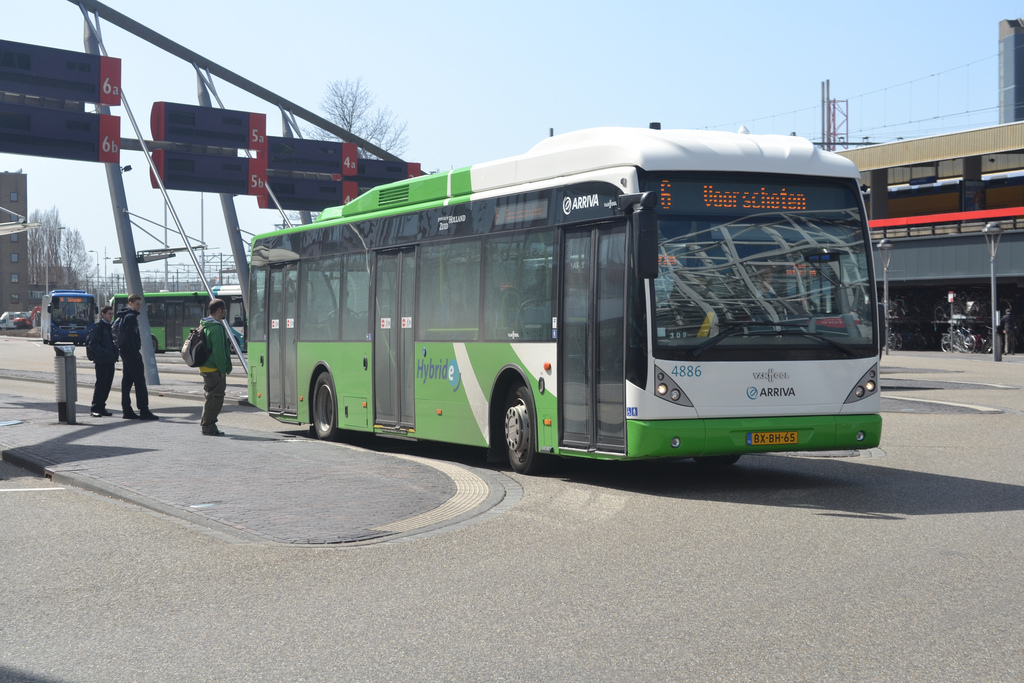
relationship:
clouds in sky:
[365, 21, 608, 132] [716, 36, 768, 75]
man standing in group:
[195, 298, 231, 436] [89, 288, 247, 436]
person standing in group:
[113, 290, 157, 420] [89, 288, 247, 436]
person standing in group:
[81, 292, 121, 416] [89, 288, 247, 436]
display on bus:
[648, 176, 869, 222] [639, 153, 886, 234]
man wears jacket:
[177, 289, 242, 430] [177, 289, 242, 430]